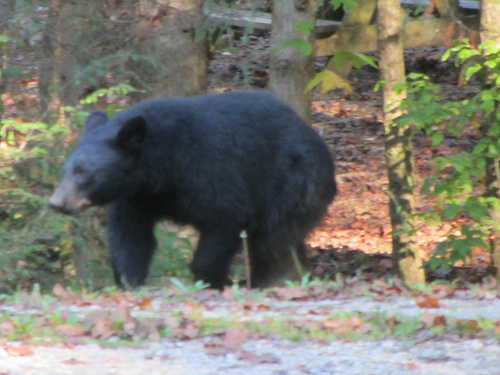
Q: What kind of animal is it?
A: Bear.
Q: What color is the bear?
A: Black.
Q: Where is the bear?
A: In the wilderness.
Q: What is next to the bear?
A: A tree.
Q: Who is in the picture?
A: A bear.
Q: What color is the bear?
A: Black.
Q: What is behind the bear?
A: Trees.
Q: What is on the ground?
A: Leaves.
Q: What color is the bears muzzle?
A: Light brown.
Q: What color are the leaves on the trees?
A: Green.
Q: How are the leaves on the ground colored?
A: Brown.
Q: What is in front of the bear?
A: A path.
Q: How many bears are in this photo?
A: One.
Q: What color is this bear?
A: Black.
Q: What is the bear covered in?
A: Fur.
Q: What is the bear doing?
A: Walking.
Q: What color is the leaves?
A: Green.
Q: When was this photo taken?
A: Outside, during the daytime.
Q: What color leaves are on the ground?
A: Brown.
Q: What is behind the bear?
A: Tree trunks.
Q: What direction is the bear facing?
A: The left.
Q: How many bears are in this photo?
A: One.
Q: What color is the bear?
A: Black.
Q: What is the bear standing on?
A: The ground.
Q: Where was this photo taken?
A: Near a bear.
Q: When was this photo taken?
A: Outside, during the daytime.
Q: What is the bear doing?
A: Walking through a forest.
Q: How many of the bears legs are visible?
A: Three.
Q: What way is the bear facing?
A: Left.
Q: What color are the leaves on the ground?
A: Brown.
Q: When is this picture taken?
A: Daytime.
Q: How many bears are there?
A: One.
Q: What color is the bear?
A: Black.